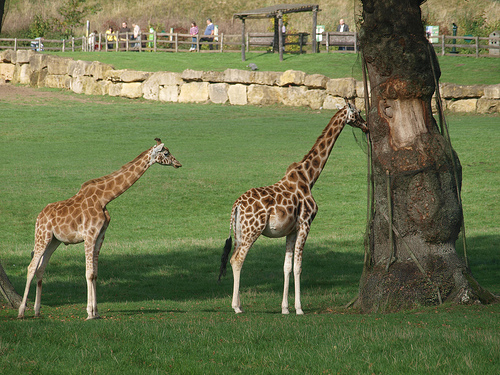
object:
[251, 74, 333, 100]
brick wall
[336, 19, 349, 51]
man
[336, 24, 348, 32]
gray jacket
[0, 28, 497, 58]
fence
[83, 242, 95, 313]
arms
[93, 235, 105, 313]
arms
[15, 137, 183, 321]
giraffe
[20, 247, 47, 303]
his legs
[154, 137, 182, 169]
head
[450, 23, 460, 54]
telescope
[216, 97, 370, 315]
animals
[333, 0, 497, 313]
tree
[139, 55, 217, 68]
grass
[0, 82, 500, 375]
enclosure